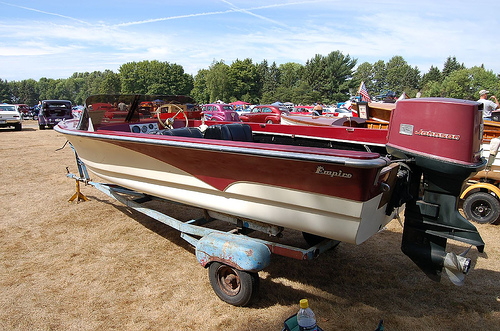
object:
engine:
[385, 97, 486, 177]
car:
[153, 101, 203, 120]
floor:
[288, 144, 380, 162]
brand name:
[315, 166, 352, 179]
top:
[300, 298, 310, 308]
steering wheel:
[157, 104, 188, 130]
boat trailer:
[66, 144, 342, 306]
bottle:
[295, 298, 319, 331]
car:
[239, 105, 289, 124]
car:
[201, 104, 240, 122]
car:
[38, 100, 74, 130]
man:
[476, 90, 499, 121]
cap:
[479, 89, 490, 96]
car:
[0, 104, 23, 131]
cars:
[290, 106, 339, 117]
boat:
[53, 94, 485, 286]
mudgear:
[196, 232, 271, 273]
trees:
[0, 51, 500, 105]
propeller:
[444, 245, 478, 287]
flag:
[358, 80, 372, 104]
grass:
[1, 122, 500, 331]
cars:
[0, 100, 500, 226]